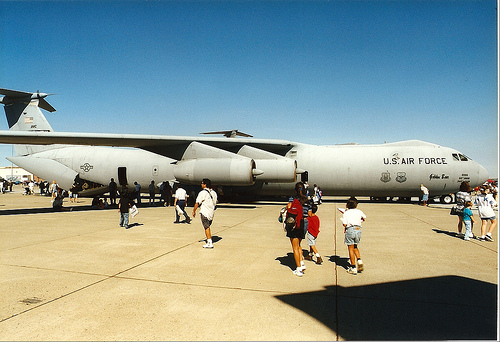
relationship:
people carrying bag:
[110, 170, 143, 230] [128, 200, 138, 216]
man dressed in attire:
[186, 166, 225, 248] [191, 186, 221, 232]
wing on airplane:
[0, 82, 63, 134] [4, 77, 496, 227]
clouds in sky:
[210, 53, 290, 120] [316, 21, 375, 70]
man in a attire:
[186, 166, 225, 248] [195, 187, 220, 231]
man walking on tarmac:
[186, 166, 225, 248] [81, 263, 299, 323]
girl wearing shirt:
[461, 200, 473, 242] [462, 207, 471, 221]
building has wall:
[1, 165, 36, 182] [2, 166, 38, 186]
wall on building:
[0, 165, 35, 185] [0, 165, 34, 183]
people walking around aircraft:
[1, 170, 498, 273] [0, 79, 493, 205]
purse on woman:
[279, 212, 296, 231] [286, 174, 311, 284]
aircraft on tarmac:
[0, 79, 493, 205] [38, 199, 495, 339]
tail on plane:
[2, 84, 91, 190] [12, 94, 52, 127]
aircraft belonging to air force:
[0, 79, 494, 199] [379, 147, 452, 170]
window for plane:
[451, 149, 475, 161] [1, 85, 498, 217]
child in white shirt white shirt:
[335, 197, 366, 276] [340, 204, 365, 226]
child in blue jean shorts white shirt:
[335, 197, 366, 276] [340, 204, 365, 226]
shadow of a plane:
[4, 197, 268, 222] [2, 72, 498, 222]